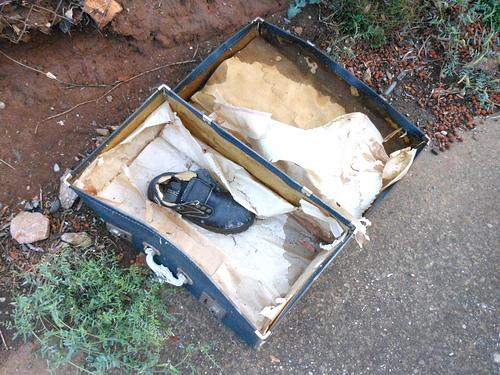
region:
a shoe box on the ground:
[12, 7, 478, 358]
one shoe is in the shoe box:
[60, 23, 425, 336]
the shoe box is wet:
[187, 15, 447, 210]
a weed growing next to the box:
[15, 248, 165, 363]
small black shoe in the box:
[140, 152, 260, 235]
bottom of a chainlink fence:
[1, 1, 126, 42]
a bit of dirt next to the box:
[120, 0, 305, 46]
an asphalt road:
[81, 125, 496, 366]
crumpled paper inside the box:
[161, 32, 421, 212]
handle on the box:
[142, 237, 189, 296]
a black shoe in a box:
[145, 166, 257, 236]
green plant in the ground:
[12, 243, 190, 371]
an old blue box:
[61, 7, 434, 347]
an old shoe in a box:
[140, 165, 257, 231]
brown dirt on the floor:
[1, 0, 297, 227]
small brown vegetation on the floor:
[326, 0, 497, 155]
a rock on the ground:
[5, 206, 52, 242]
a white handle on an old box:
[138, 241, 188, 286]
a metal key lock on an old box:
[195, 287, 230, 322]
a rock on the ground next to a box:
[61, 224, 94, 248]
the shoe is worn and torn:
[145, 169, 252, 233]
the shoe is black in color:
[149, 163, 253, 235]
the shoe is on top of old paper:
[148, 168, 251, 235]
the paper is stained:
[91, 104, 347, 349]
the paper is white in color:
[96, 103, 346, 335]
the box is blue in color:
[80, 82, 362, 355]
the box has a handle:
[142, 245, 183, 288]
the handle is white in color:
[146, 246, 186, 293]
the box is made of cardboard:
[69, 85, 360, 347]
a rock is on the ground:
[9, 209, 48, 244]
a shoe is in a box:
[152, 165, 251, 232]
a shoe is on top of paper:
[153, 165, 253, 234]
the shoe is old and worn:
[151, 166, 253, 238]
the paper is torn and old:
[94, 104, 348, 330]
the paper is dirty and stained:
[82, 98, 344, 327]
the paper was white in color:
[91, 101, 346, 335]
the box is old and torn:
[70, 73, 356, 347]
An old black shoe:
[154, 174, 259, 239]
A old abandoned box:
[90, 77, 399, 290]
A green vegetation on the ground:
[19, 225, 171, 373]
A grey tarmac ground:
[317, 319, 458, 365]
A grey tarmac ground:
[379, 221, 461, 315]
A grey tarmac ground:
[460, 138, 497, 291]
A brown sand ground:
[20, 64, 100, 155]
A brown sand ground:
[58, 11, 165, 101]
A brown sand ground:
[149, 6, 221, 51]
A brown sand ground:
[1, 216, 39, 372]